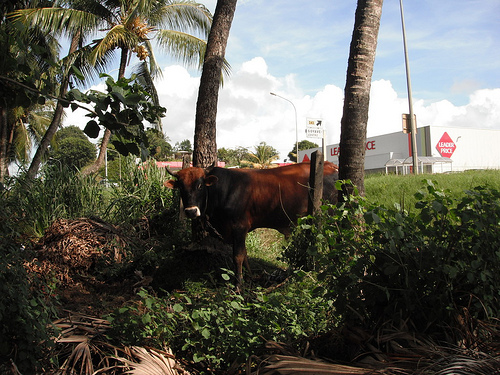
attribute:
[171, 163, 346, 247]
cow — close, here, staring, wide, standing, brown, thick, fat, red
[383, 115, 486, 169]
building — white, far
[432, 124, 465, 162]
sign — red, white, diamond, close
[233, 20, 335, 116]
sky — above, light, clear, high, close, here, blue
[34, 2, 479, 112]
sky — blue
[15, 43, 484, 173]
clouds — white